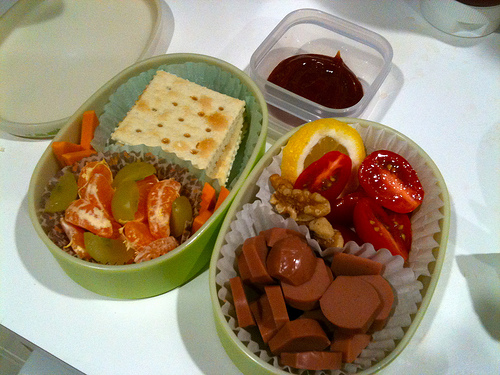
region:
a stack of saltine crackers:
[122, 75, 243, 170]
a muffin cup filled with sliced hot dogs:
[228, 234, 393, 366]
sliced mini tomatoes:
[313, 149, 428, 254]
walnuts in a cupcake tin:
[268, 174, 333, 243]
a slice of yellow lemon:
[284, 128, 361, 165]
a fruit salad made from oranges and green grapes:
[46, 176, 203, 239]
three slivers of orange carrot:
[196, 182, 228, 226]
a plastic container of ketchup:
[271, 48, 363, 105]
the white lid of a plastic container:
[2, 7, 166, 111]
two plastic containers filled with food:
[25, 70, 435, 367]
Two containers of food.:
[18, 15, 476, 370]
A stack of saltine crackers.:
[123, 67, 253, 179]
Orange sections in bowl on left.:
[46, 149, 211, 261]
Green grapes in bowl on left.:
[46, 147, 208, 261]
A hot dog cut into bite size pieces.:
[217, 213, 401, 373]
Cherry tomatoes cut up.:
[303, 142, 429, 256]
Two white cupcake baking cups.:
[215, 115, 445, 368]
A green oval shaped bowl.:
[26, 41, 275, 291]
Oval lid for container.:
[10, 5, 170, 135]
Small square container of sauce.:
[255, 2, 394, 118]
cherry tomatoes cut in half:
[352, 147, 425, 251]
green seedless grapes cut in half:
[112, 149, 149, 227]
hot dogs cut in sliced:
[240, 231, 370, 373]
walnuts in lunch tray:
[263, 172, 341, 242]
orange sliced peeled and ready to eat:
[80, 158, 120, 237]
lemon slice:
[287, 107, 366, 188]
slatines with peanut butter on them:
[108, 67, 258, 183]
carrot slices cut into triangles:
[52, 104, 115, 179]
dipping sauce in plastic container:
[248, 4, 395, 120]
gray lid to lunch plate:
[8, 1, 237, 160]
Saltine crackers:
[100, 58, 260, 191]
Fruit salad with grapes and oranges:
[44, 159, 196, 279]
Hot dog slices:
[219, 230, 399, 373]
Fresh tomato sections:
[289, 145, 449, 266]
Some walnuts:
[270, 169, 343, 252]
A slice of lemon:
[282, 116, 369, 186]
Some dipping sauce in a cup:
[272, 17, 409, 129]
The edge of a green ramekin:
[28, 252, 145, 324]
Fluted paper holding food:
[420, 200, 448, 285]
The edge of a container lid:
[116, 15, 201, 47]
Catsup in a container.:
[219, 37, 341, 133]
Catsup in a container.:
[215, 24, 357, 214]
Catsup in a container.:
[253, 31, 338, 98]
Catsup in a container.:
[263, 31, 403, 118]